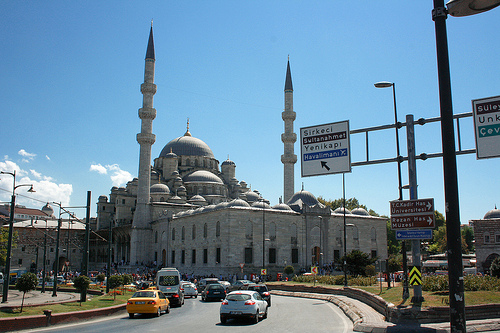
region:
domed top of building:
[137, 116, 257, 213]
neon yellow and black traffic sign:
[404, 261, 428, 286]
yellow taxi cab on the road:
[127, 284, 172, 311]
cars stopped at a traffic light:
[107, 264, 275, 331]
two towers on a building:
[129, 9, 299, 197]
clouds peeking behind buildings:
[8, 130, 140, 201]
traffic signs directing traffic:
[385, 188, 442, 251]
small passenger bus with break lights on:
[155, 259, 182, 300]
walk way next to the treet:
[303, 283, 374, 328]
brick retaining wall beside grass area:
[347, 284, 392, 331]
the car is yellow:
[117, 286, 169, 324]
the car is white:
[211, 281, 268, 320]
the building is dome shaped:
[125, 119, 378, 266]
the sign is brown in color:
[382, 197, 434, 229]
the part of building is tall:
[133, 24, 165, 220]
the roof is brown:
[15, 199, 45, 220]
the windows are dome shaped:
[170, 219, 230, 260]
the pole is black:
[427, 33, 470, 285]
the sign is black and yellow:
[398, 261, 426, 291]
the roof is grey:
[166, 130, 217, 160]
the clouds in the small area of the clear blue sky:
[0, 1, 499, 219]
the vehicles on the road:
[10, 265, 271, 322]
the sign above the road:
[298, 119, 352, 179]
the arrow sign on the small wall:
[310, 267, 317, 287]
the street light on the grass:
[372, 80, 409, 300]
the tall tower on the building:
[130, 17, 157, 267]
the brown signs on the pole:
[389, 197, 434, 226]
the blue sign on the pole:
[394, 228, 433, 240]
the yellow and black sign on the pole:
[407, 264, 421, 286]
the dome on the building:
[157, 135, 216, 158]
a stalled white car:
[221, 291, 267, 320]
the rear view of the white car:
[221, 292, 256, 322]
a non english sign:
[298, 125, 351, 175]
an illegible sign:
[390, 199, 436, 241]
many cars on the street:
[132, 269, 257, 319]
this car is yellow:
[128, 289, 169, 314]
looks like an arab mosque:
[113, 126, 383, 274]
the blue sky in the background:
[173, 4, 386, 39]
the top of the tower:
[146, 19, 155, 63]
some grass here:
[48, 304, 84, 311]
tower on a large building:
[132, 16, 162, 223]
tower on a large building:
[276, 48, 296, 203]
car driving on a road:
[210, 283, 277, 328]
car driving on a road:
[121, 283, 171, 319]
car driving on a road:
[198, 279, 228, 304]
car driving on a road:
[244, 282, 275, 305]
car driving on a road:
[177, 280, 202, 301]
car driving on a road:
[152, 263, 189, 308]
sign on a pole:
[405, 263, 424, 292]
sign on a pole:
[381, 194, 443, 248]